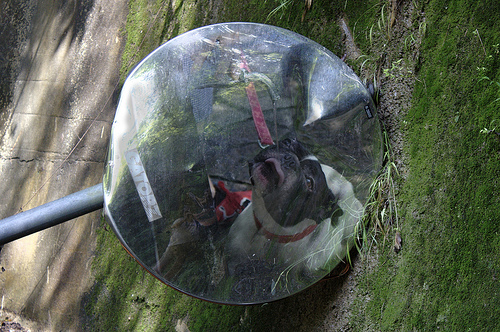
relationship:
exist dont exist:
[35, 23, 37, 31] [35, 23, 37, 31]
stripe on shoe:
[240, 54, 278, 145] [207, 183, 254, 224]